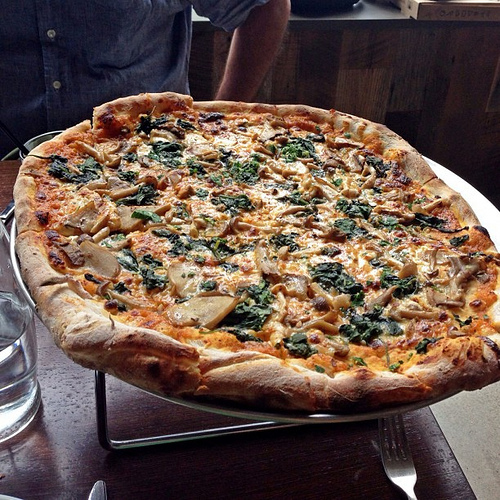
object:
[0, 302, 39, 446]
liquid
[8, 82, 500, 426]
pizza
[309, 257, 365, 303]
spinach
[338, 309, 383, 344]
spinach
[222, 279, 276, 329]
spinach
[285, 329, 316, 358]
spinach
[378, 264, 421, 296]
spinach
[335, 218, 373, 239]
spinach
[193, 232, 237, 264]
spinach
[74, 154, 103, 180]
spinach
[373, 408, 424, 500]
fork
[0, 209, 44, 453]
container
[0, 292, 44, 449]
water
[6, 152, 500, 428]
tray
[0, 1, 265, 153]
shirt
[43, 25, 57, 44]
button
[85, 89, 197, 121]
dry crust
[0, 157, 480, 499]
table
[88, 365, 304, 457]
stand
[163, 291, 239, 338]
mushroom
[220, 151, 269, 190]
spinach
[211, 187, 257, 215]
spinach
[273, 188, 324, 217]
spinach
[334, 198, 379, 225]
spinach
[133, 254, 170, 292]
spinach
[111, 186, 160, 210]
spinach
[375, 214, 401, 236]
spinach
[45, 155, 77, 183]
spinach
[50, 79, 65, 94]
button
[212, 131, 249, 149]
toppings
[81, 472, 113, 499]
knife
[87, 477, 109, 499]
top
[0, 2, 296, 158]
man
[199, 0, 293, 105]
forearm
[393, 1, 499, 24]
box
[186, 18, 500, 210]
wall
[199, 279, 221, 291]
spinach